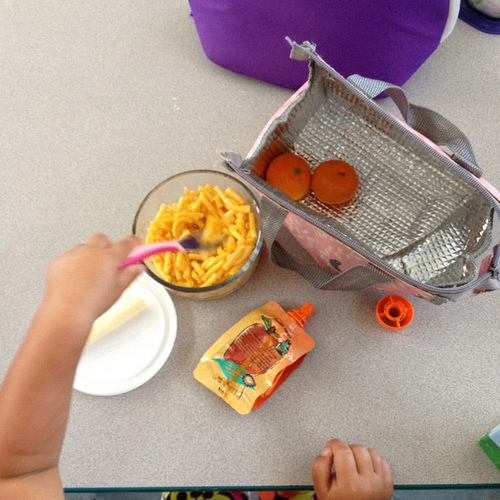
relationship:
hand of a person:
[302, 434, 400, 496] [0, 232, 396, 498]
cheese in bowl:
[190, 250, 216, 278] [143, 185, 244, 274]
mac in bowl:
[161, 204, 232, 264] [143, 185, 244, 274]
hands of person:
[43, 231, 145, 318] [0, 232, 396, 498]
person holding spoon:
[0, 232, 396, 498] [122, 227, 211, 283]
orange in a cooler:
[312, 159, 358, 203] [217, 37, 497, 297]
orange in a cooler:
[267, 153, 308, 199] [217, 37, 497, 297]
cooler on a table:
[188, 1, 460, 97] [2, 2, 498, 487]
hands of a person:
[42, 231, 393, 495] [2, 232, 396, 498]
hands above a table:
[42, 231, 393, 495] [2, 2, 498, 487]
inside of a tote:
[220, 43, 492, 287] [213, 39, 498, 305]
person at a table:
[2, 232, 396, 498] [2, 2, 498, 487]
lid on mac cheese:
[72, 272, 177, 394] [143, 184, 253, 287]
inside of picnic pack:
[220, 43, 492, 287] [211, 36, 499, 306]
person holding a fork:
[2, 232, 396, 498] [122, 230, 228, 263]